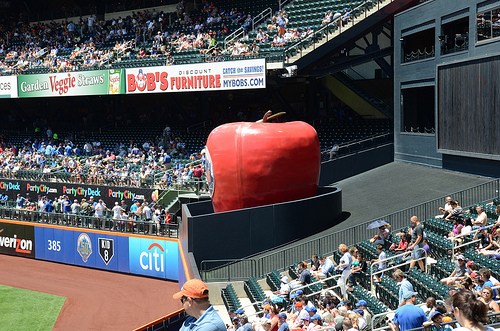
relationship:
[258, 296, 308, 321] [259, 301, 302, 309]
spectators with caps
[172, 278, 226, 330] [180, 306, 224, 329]
fan in shirt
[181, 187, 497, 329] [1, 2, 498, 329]
fans in stadium